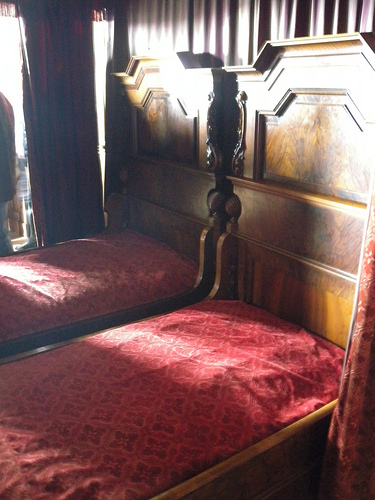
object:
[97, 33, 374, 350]
bed post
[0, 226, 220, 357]
sheet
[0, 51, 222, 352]
bed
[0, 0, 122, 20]
rail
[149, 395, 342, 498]
frame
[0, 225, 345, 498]
pattern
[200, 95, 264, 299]
decoration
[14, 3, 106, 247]
curtain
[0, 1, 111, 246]
window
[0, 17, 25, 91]
sky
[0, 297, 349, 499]
sheet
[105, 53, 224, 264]
head board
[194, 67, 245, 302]
finials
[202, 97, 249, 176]
carving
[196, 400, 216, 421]
floral designs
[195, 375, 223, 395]
designs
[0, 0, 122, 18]
fringes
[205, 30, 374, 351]
head board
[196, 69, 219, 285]
post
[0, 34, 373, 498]
bed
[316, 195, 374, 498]
drapes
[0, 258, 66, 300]
sunlight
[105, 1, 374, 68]
drapes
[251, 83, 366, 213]
design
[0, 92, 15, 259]
person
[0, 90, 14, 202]
shirt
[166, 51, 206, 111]
sunlight